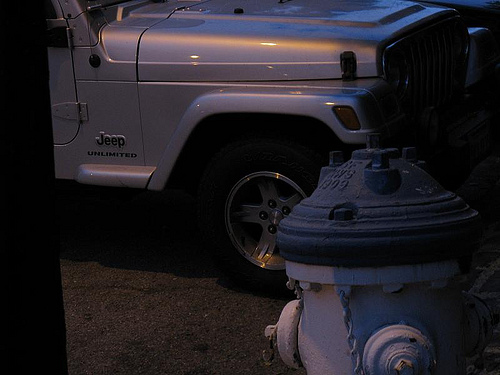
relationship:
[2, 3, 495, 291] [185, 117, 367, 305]
jeep has wheel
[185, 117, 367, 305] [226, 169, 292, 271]
wheel seen center part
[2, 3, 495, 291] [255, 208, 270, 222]
machine seen a nut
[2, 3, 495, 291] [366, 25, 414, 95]
jeep has front light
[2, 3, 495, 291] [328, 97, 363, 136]
jeep has light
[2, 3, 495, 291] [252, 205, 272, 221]
machine has big bolt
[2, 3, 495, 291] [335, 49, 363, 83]
jeep has black mark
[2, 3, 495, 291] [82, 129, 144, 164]
jeep has name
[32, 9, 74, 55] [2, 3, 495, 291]
mirror on side jeep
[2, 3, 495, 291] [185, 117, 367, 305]
jeep has tires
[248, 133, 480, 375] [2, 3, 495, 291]
hydran next to jeep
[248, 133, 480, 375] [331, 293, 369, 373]
hydrant has chain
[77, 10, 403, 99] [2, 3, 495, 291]
light on jeep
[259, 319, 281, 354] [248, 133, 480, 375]
bolt on pillar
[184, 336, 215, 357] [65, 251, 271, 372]
black object in sand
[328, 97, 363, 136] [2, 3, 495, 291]
indicator on side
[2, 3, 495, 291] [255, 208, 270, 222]
jeep has nut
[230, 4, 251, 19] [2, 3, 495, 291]
object on jeep